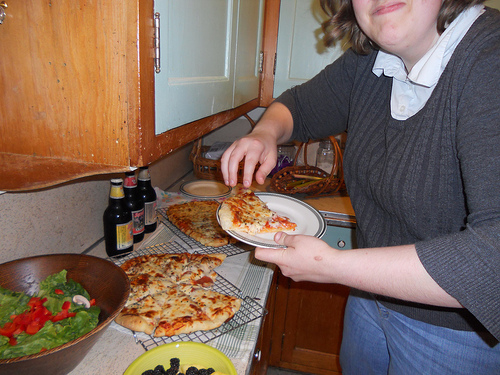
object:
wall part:
[0, 173, 110, 265]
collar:
[370, 1, 487, 87]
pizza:
[112, 253, 243, 338]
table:
[17, 191, 362, 375]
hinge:
[151, 10, 161, 75]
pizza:
[218, 189, 298, 234]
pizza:
[167, 198, 238, 247]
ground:
[434, 142, 441, 163]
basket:
[0, 253, 132, 375]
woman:
[221, 0, 497, 375]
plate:
[216, 187, 326, 247]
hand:
[72, 294, 90, 309]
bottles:
[103, 165, 157, 258]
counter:
[66, 168, 358, 373]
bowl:
[121, 340, 239, 375]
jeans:
[337, 294, 498, 374]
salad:
[0, 268, 100, 359]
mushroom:
[50, 299, 77, 323]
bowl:
[0, 251, 130, 375]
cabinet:
[0, 0, 348, 196]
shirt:
[271, 6, 500, 317]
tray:
[97, 240, 269, 352]